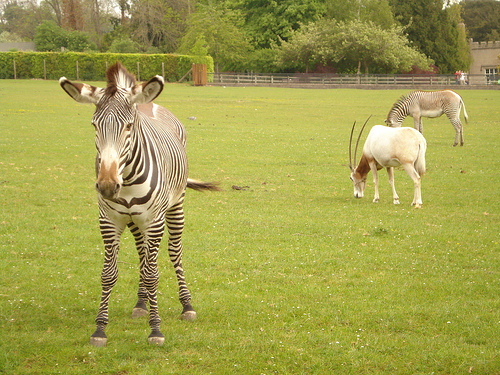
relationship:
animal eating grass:
[345, 113, 429, 211] [0, 81, 499, 374]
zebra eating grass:
[386, 88, 471, 150] [0, 81, 499, 374]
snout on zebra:
[94, 174, 120, 197] [54, 61, 225, 351]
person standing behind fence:
[453, 69, 462, 84] [201, 72, 499, 88]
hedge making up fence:
[0, 49, 215, 85] [201, 72, 499, 88]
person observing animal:
[453, 69, 462, 84] [345, 113, 429, 211]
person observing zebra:
[462, 70, 471, 84] [54, 61, 225, 351]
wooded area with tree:
[1, 0, 499, 374] [173, 0, 252, 73]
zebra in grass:
[54, 61, 225, 351] [0, 81, 499, 374]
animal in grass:
[345, 113, 429, 211] [0, 81, 499, 374]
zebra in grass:
[386, 88, 471, 150] [0, 81, 499, 374]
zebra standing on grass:
[54, 61, 225, 351] [0, 81, 499, 374]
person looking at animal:
[453, 69, 462, 84] [345, 113, 429, 211]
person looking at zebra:
[462, 70, 471, 84] [54, 61, 225, 351]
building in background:
[467, 34, 499, 82] [0, 0, 499, 85]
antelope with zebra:
[345, 113, 429, 211] [54, 61, 225, 351]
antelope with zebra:
[345, 113, 429, 211] [386, 88, 471, 150]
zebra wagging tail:
[54, 61, 225, 351] [185, 174, 224, 194]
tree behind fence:
[173, 0, 252, 73] [201, 72, 499, 88]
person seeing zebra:
[453, 69, 462, 84] [54, 61, 225, 351]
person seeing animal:
[462, 70, 471, 84] [345, 113, 429, 211]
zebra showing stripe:
[54, 61, 225, 351] [116, 124, 159, 211]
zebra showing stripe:
[54, 61, 225, 351] [116, 122, 151, 189]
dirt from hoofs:
[147, 334, 165, 346] [146, 329, 164, 344]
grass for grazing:
[0, 81, 499, 374] [353, 193, 366, 201]